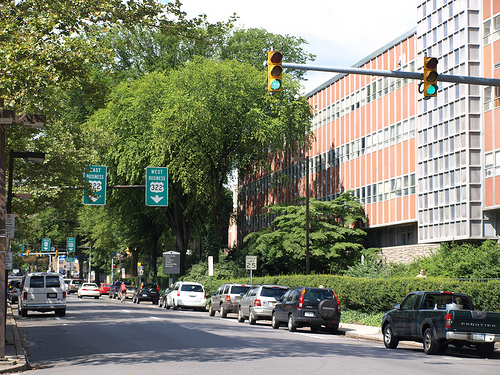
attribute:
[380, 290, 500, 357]
truck — dark colored, parked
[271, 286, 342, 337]
honda — black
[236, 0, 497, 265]
building — large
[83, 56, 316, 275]
trees — green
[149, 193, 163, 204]
arrow — white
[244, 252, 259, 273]
speed limit sign — white, 25, black, showing 25, saying 25 mph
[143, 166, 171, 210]
sign — green, white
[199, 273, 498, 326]
hedge — growing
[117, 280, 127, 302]
person — riding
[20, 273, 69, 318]
van — white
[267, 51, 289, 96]
street sign — green, tall, hanging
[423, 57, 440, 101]
street sign — green